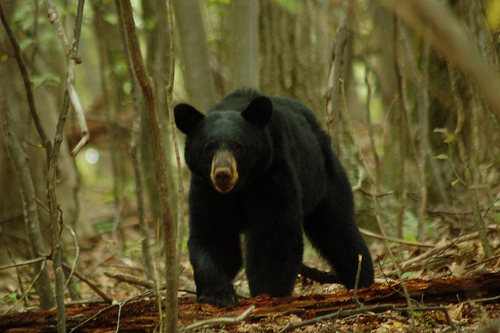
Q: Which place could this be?
A: It is a forest.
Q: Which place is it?
A: It is a forest.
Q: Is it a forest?
A: Yes, it is a forest.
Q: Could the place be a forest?
A: Yes, it is a forest.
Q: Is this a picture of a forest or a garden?
A: It is showing a forest.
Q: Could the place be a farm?
A: No, it is a forest.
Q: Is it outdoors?
A: Yes, it is outdoors.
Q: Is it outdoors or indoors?
A: It is outdoors.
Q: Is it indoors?
A: No, it is outdoors.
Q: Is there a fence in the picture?
A: No, there are no fences.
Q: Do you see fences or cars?
A: No, there are no fences or cars.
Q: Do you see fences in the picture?
A: No, there are no fences.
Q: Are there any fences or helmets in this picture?
A: No, there are no fences or helmets.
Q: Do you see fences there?
A: No, there are no fences.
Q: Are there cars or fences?
A: No, there are no fences or cars.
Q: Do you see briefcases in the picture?
A: No, there are no briefcases.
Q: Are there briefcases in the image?
A: No, there are no briefcases.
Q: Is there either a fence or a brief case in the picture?
A: No, there are no briefcases or fences.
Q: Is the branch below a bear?
A: Yes, the branch is below a bear.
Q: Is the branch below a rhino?
A: No, the branch is below a bear.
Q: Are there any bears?
A: Yes, there is a bear.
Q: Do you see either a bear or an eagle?
A: Yes, there is a bear.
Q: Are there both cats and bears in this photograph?
A: No, there is a bear but no cats.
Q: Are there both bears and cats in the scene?
A: No, there is a bear but no cats.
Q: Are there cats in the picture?
A: No, there are no cats.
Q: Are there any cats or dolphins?
A: No, there are no cats or dolphins.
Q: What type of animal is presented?
A: The animal is a bear.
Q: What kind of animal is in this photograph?
A: The animal is a bear.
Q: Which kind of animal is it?
A: The animal is a bear.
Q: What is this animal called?
A: This is a bear.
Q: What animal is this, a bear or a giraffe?
A: This is a bear.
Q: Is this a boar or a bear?
A: This is a bear.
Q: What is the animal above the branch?
A: The animal is a bear.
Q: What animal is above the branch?
A: The animal is a bear.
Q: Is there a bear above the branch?
A: Yes, there is a bear above the branch.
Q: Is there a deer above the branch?
A: No, there is a bear above the branch.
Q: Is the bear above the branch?
A: Yes, the bear is above the branch.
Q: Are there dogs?
A: No, there are no dogs.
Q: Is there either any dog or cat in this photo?
A: No, there are no dogs or cats.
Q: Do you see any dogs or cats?
A: No, there are no dogs or cats.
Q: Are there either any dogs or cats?
A: No, there are no dogs or cats.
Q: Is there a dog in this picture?
A: No, there are no dogs.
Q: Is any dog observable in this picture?
A: No, there are no dogs.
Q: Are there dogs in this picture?
A: No, there are no dogs.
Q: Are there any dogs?
A: No, there are no dogs.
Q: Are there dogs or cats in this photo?
A: No, there are no dogs or cats.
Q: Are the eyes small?
A: Yes, the eyes are small.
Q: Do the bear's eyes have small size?
A: Yes, the eyes are small.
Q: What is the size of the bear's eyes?
A: The eyes are small.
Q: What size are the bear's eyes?
A: The eyes are small.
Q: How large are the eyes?
A: The eyes are small.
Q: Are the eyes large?
A: No, the eyes are small.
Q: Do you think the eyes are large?
A: No, the eyes are small.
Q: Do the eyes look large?
A: No, the eyes are small.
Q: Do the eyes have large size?
A: No, the eyes are small.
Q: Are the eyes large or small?
A: The eyes are small.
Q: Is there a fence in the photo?
A: No, there are no fences.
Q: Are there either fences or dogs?
A: No, there are no fences or dogs.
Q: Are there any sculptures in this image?
A: No, there are no sculptures.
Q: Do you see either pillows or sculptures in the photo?
A: No, there are no sculptures or pillows.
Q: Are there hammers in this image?
A: No, there are no hammers.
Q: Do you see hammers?
A: No, there are no hammers.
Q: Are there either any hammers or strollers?
A: No, there are no hammers or strollers.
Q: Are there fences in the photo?
A: No, there are no fences.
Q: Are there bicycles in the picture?
A: No, there are no bicycles.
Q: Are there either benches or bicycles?
A: No, there are no bicycles or benches.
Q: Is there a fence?
A: No, there are no fences.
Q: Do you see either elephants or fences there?
A: No, there are no fences or elephants.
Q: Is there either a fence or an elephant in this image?
A: No, there are no fences or elephants.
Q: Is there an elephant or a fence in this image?
A: No, there are no fences or elephants.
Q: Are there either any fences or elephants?
A: No, there are no fences or elephants.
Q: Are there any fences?
A: No, there are no fences.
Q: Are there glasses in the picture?
A: No, there are no glasses.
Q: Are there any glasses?
A: No, there are no glasses.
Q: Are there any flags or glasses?
A: No, there are no glasses or flags.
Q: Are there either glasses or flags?
A: No, there are no glasses or flags.